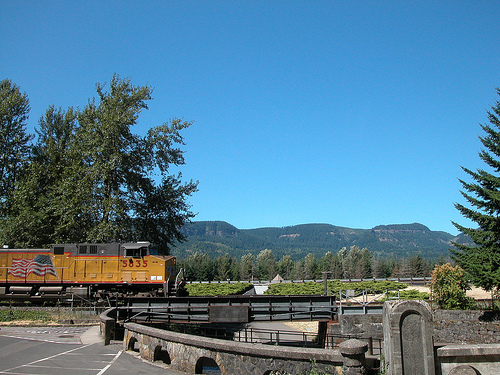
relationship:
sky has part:
[345, 96, 385, 146] [325, 67, 384, 142]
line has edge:
[152, 327, 374, 373] [134, 332, 334, 352]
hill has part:
[176, 219, 479, 262] [286, 204, 350, 281]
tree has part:
[0, 76, 203, 248] [160, 115, 204, 253]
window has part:
[124, 244, 146, 259] [123, 240, 147, 260]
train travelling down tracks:
[3, 240, 186, 305] [5, 292, 382, 311]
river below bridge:
[158, 351, 318, 373] [105, 296, 340, 324]